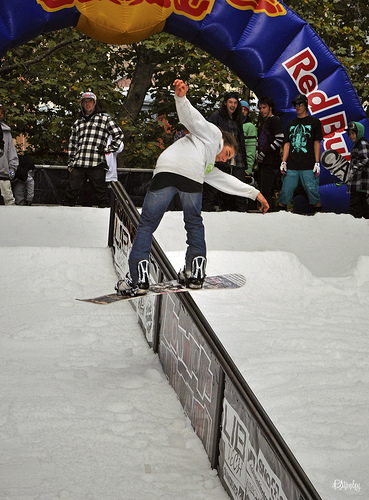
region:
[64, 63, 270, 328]
Man on a snowboard.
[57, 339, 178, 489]
Snow on the ground.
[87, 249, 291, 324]
Snowboard on the rail.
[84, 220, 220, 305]
Boots on the man.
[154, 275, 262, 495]
Wall in the snow.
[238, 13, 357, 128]
Sign in the background.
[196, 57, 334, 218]
People in the background.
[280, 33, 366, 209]
Red Bull logo.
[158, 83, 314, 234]
White shirt on the man.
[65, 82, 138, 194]
man in a plaid jacket.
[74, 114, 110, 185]
a guy wearing a checkered shirt.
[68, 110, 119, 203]
a guy wearing a plaid shirt.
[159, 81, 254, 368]
a person snowboarding down a rail.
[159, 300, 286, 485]
signage hanging from a rail.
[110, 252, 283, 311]
a person standing on a snowboard.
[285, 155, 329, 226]
a person wearing green/blue shorts in snow.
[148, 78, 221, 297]
A peson balancing down a rail.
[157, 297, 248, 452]
a rail displaying signage.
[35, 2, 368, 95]
Advertisement inflated above people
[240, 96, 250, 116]
a person wearing a blue hat.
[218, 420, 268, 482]
name on side of barrier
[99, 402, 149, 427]
tiny spots in the snow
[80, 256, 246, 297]
skate board balancing on wall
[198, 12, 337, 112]
large blue plastic banner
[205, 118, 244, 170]
man's head turned backwards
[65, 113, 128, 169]
black and white plaid shirt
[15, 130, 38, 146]
yellow and white color on wall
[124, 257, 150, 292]
high top black and white sneakers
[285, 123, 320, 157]
large green design on shirt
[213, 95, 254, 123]
black fur on jacket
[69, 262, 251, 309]
snowboard on black railing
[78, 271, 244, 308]
multicolored snowboard on railing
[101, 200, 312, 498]
advertisements underneath grinding railing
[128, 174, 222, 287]
snowboarder wearing blue jeans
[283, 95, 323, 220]
person wearing black and green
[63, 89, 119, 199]
person wearing black plad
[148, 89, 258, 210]
person wearing white long sleeve shirt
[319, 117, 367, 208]
person holding white snowboard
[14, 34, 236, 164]
green leaves on trees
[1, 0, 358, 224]
blue and yellow starting line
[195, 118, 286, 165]
the head of a man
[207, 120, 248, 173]
the face of a man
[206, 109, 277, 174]
the hair of a man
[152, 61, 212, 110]
the hand of a man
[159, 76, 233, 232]
the arm of a man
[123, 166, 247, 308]
the legs of a man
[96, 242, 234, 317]
the feet of a man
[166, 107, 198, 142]
the elbow of a man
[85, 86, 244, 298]
a man wearing a shirt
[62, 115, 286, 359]
a boy on a skteboard